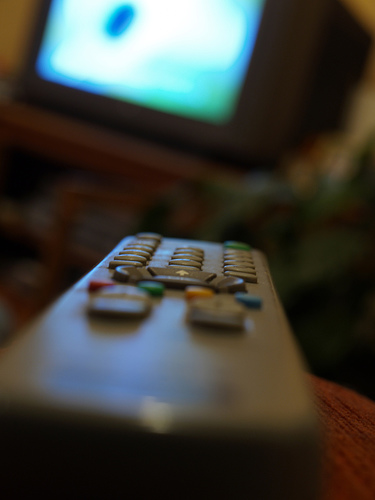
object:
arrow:
[174, 268, 190, 279]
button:
[185, 286, 213, 301]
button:
[86, 278, 119, 296]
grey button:
[222, 268, 256, 283]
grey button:
[131, 229, 160, 244]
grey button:
[106, 258, 142, 273]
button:
[185, 312, 245, 336]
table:
[0, 284, 374, 498]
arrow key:
[146, 264, 216, 285]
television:
[26, 0, 272, 157]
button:
[134, 279, 164, 302]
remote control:
[0, 229, 324, 499]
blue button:
[234, 291, 261, 311]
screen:
[34, 0, 264, 126]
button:
[225, 240, 249, 252]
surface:
[0, 284, 374, 498]